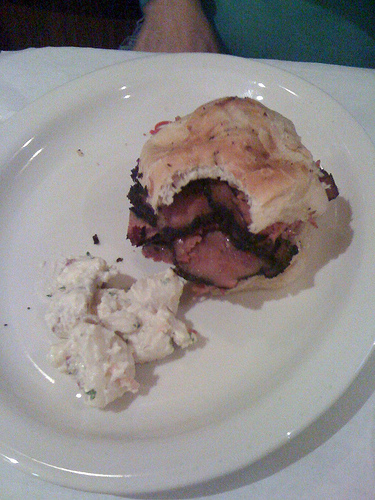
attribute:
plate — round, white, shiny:
[7, 78, 361, 480]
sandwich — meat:
[124, 93, 340, 292]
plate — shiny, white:
[3, 48, 363, 494]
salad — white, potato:
[42, 246, 198, 409]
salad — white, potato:
[51, 254, 118, 288]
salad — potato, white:
[137, 266, 192, 353]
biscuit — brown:
[138, 95, 315, 234]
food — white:
[48, 254, 193, 411]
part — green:
[86, 386, 98, 401]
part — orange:
[189, 326, 197, 336]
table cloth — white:
[3, 45, 358, 495]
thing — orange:
[152, 121, 169, 131]